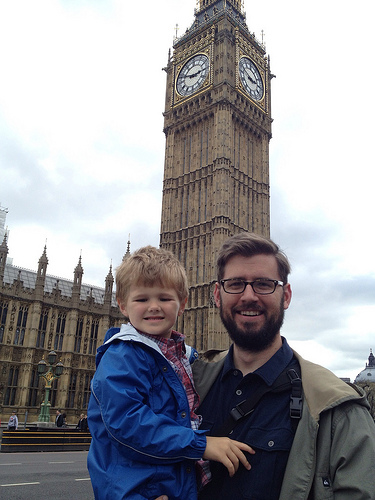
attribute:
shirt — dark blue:
[201, 349, 322, 484]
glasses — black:
[227, 269, 288, 301]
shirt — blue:
[203, 363, 282, 496]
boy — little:
[107, 238, 233, 495]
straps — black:
[221, 361, 303, 440]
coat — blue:
[85, 320, 215, 498]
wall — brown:
[158, 128, 272, 239]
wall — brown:
[172, 158, 284, 240]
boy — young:
[58, 230, 220, 499]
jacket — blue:
[79, 324, 229, 492]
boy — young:
[85, 245, 255, 497]